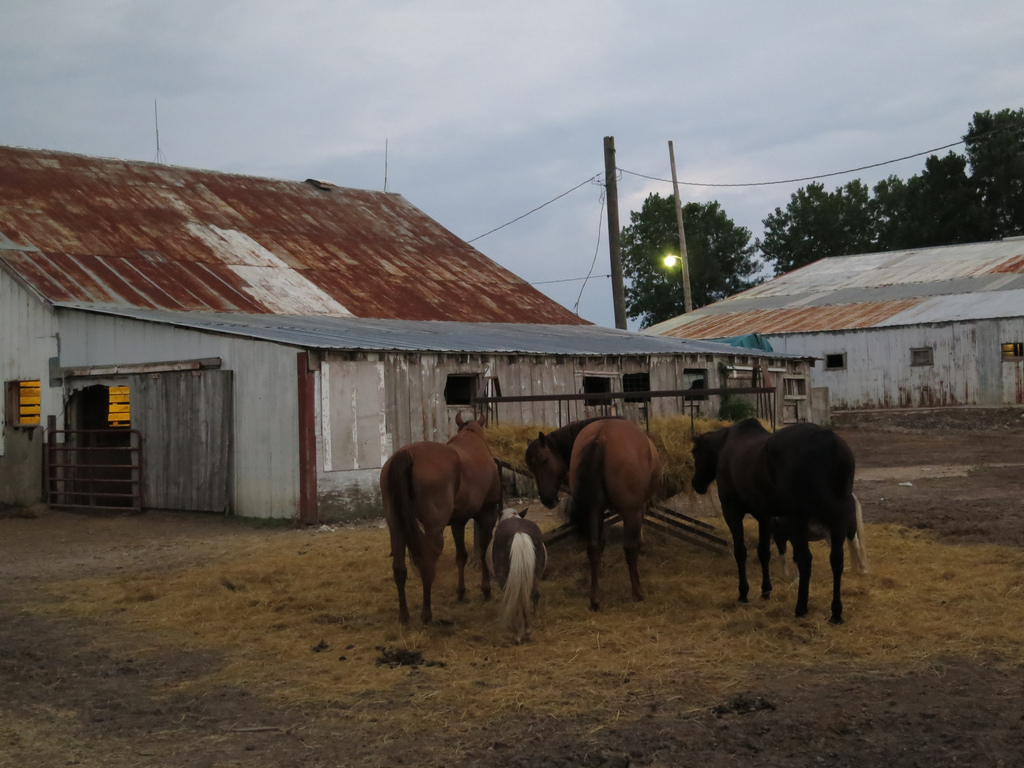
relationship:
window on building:
[814, 352, 849, 369] [637, 228, 1005, 416]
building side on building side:
[766, 319, 1021, 415] [813, 321, 1019, 427]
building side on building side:
[0, 261, 310, 520] [9, 302, 340, 545]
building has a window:
[0, 145, 829, 523] [588, 372, 611, 404]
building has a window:
[0, 145, 829, 523] [615, 369, 648, 401]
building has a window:
[640, 240, 1023, 410] [901, 339, 941, 378]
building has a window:
[640, 228, 1017, 440] [997, 330, 1021, 357]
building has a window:
[0, 145, 829, 523] [19, 376, 40, 431]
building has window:
[0, 145, 829, 523] [73, 383, 130, 511]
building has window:
[0, 145, 829, 523] [332, 365, 389, 471]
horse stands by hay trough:
[687, 418, 846, 624] [438, 384, 781, 574]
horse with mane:
[526, 415, 661, 610] [512, 409, 627, 459]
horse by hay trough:
[378, 412, 503, 619] [435, 365, 794, 527]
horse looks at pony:
[526, 412, 662, 609] [481, 500, 543, 633]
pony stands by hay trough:
[488, 506, 534, 649] [443, 374, 797, 561]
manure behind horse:
[377, 646, 431, 681] [364, 393, 500, 629]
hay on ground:
[76, 523, 991, 676] [36, 523, 994, 738]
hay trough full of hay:
[466, 393, 752, 556] [463, 396, 735, 495]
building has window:
[0, 145, 829, 523] [57, 252, 699, 467]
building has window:
[3, 130, 833, 511] [690, 368, 709, 400]